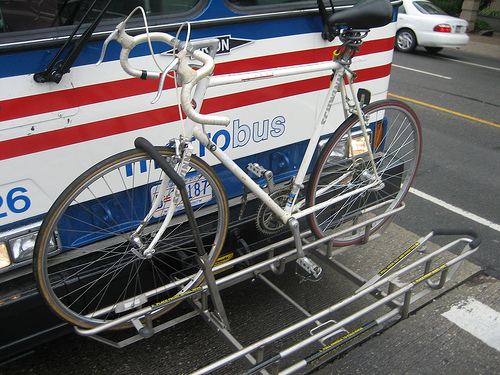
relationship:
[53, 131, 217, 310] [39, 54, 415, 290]
wheel of bicycle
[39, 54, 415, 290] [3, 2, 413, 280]
bicycle attached to bus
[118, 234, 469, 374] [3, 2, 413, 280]
bike rack on metrobus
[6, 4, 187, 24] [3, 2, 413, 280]
window of bus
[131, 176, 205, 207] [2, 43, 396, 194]
license plate on bus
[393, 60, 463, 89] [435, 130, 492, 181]
line on road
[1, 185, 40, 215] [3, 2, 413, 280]
number of bus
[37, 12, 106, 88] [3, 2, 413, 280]
windshield wiper of bus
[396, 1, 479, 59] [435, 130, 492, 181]
car across road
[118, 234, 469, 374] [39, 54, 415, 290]
bike rack of bicycle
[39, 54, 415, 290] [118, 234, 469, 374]
bicycle on bike rack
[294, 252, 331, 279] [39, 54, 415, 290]
pedal of bicycle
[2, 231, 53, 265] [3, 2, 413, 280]
headlights on bus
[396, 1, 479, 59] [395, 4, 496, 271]
car in background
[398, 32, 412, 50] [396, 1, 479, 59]
hubcap of car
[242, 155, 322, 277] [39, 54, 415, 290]
pedals of bicycle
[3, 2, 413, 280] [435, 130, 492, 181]
bus on road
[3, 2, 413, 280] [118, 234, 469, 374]
bus has bike rack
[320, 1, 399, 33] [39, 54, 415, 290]
seat of bicycle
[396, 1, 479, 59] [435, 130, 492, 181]
car on road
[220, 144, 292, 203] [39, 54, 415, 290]
tube of bicycle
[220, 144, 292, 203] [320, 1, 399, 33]
tube of seat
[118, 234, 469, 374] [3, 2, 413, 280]
bike rack attached to bus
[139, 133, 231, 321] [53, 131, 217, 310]
harness over wheel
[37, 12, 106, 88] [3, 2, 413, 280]
windshield wiper attached to bus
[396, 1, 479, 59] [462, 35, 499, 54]
car at curb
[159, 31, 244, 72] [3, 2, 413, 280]
manufacturer of bus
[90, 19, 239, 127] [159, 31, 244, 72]
handle bars cover manufacturer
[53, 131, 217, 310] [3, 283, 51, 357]
wheel covering bumper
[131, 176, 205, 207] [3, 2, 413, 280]
license plate on bus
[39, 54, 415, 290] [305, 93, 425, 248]
bicycle has tire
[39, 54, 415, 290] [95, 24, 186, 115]
bicycle has breaks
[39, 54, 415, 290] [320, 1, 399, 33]
bicycle has seat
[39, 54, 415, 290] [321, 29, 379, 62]
bicycle has chain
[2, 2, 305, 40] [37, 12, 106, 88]
windshield has windshield wiper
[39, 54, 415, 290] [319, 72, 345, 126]
bicycle reads schwinn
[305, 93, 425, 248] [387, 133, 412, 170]
tire has spokes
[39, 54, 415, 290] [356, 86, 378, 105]
bicycle has reflector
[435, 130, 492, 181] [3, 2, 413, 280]
road beside bus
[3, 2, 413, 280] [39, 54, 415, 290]
bus behind bicycle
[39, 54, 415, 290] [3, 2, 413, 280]
bicycle on bus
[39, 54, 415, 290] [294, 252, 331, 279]
bicycle has pedal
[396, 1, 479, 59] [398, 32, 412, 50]
car has hubcap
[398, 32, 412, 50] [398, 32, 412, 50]
hubcap has hubcap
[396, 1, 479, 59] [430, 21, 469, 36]
car has tail lights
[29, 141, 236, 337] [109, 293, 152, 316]
front tire has reflector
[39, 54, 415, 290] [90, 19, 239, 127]
bicycle has handle bars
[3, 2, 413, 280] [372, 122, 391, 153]
bus has reflector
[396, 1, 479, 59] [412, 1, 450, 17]
car has back windshield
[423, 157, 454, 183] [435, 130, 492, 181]
crack in road